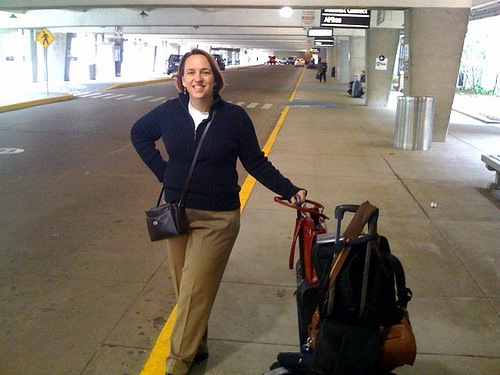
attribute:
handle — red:
[266, 189, 326, 290]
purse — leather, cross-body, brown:
[138, 188, 198, 253]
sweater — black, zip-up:
[112, 95, 306, 240]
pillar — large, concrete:
[406, 8, 459, 140]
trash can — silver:
[392, 89, 446, 156]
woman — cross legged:
[101, 44, 283, 373]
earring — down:
[185, 85, 189, 98]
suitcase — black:
[297, 202, 443, 365]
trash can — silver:
[380, 79, 449, 166]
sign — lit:
[317, 8, 376, 32]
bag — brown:
[380, 320, 421, 360]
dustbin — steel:
[387, 90, 451, 153]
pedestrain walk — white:
[73, 78, 288, 121]